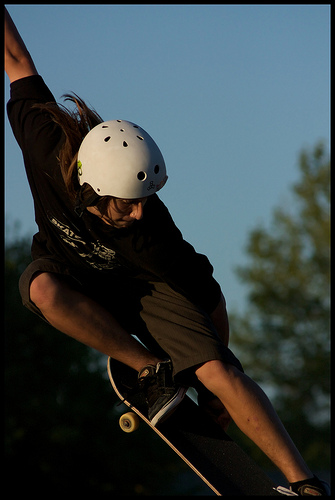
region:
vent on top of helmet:
[123, 138, 129, 155]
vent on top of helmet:
[136, 169, 145, 180]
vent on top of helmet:
[152, 164, 160, 179]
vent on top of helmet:
[106, 135, 112, 144]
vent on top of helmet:
[99, 122, 107, 127]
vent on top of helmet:
[115, 117, 126, 123]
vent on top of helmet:
[131, 122, 139, 134]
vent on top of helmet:
[118, 125, 125, 135]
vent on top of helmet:
[117, 118, 124, 124]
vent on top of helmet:
[95, 185, 102, 192]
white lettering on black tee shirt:
[35, 209, 139, 292]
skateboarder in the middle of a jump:
[9, 4, 326, 494]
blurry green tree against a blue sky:
[218, 125, 331, 451]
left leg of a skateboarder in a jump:
[183, 349, 320, 494]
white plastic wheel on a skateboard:
[113, 409, 139, 435]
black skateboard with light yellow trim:
[98, 341, 238, 494]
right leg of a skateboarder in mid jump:
[21, 261, 166, 384]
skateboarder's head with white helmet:
[63, 115, 167, 231]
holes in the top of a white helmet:
[87, 117, 165, 185]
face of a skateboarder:
[94, 186, 152, 235]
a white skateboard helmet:
[70, 120, 173, 194]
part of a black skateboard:
[104, 356, 235, 497]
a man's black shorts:
[11, 238, 239, 376]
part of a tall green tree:
[227, 140, 334, 432]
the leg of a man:
[139, 288, 304, 483]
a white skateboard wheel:
[117, 411, 135, 432]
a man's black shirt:
[7, 73, 225, 310]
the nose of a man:
[127, 198, 143, 222]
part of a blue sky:
[4, 2, 329, 110]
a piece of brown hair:
[57, 87, 102, 123]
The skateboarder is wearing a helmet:
[65, 103, 177, 212]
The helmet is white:
[70, 117, 172, 205]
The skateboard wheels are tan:
[112, 404, 148, 437]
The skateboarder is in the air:
[8, 51, 284, 497]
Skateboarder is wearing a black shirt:
[5, 68, 205, 320]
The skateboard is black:
[96, 343, 264, 498]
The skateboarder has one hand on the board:
[15, 74, 274, 454]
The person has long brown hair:
[49, 99, 154, 227]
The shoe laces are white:
[263, 480, 310, 493]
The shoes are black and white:
[127, 356, 196, 427]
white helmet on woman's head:
[73, 121, 170, 197]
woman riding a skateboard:
[5, 31, 334, 495]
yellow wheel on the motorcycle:
[112, 406, 145, 437]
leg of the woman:
[200, 357, 308, 481]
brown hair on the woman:
[36, 93, 84, 139]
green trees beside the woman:
[237, 226, 334, 352]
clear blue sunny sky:
[203, 100, 251, 159]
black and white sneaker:
[122, 353, 173, 420]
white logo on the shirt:
[44, 228, 121, 269]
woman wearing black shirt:
[33, 229, 193, 271]